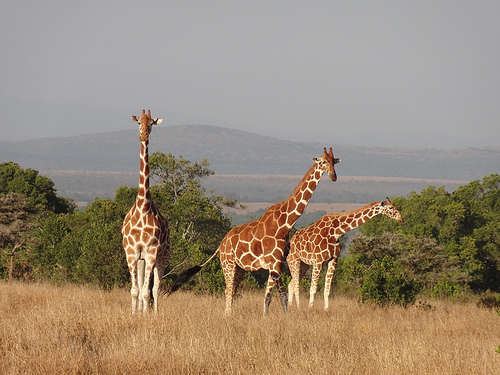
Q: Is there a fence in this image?
A: No, there are no fences.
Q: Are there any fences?
A: No, there are no fences.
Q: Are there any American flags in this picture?
A: No, there are no American flags.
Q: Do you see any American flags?
A: No, there are no American flags.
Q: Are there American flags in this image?
A: No, there are no American flags.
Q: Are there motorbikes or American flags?
A: No, there are no American flags or motorbikes.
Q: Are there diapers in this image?
A: No, there are no diapers.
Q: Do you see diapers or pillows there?
A: No, there are no diapers or pillows.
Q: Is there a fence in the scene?
A: No, there are no fences.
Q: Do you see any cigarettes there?
A: No, there are no cigarettes.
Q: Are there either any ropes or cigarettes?
A: No, there are no cigarettes or ropes.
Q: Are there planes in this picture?
A: No, there are no planes.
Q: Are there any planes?
A: No, there are no planes.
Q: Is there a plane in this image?
A: No, there are no airplanes.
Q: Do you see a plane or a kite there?
A: No, there are no airplanes or kites.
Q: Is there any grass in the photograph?
A: Yes, there is grass.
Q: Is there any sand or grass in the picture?
A: Yes, there is grass.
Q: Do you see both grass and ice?
A: No, there is grass but no ice.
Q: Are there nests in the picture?
A: No, there are no nests.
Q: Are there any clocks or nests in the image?
A: No, there are no nests or clocks.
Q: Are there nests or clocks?
A: No, there are no nests or clocks.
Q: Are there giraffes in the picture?
A: Yes, there is a giraffe.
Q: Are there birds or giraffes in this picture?
A: Yes, there is a giraffe.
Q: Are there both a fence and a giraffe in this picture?
A: No, there is a giraffe but no fences.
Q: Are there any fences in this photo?
A: No, there are no fences.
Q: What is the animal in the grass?
A: The animal is a giraffe.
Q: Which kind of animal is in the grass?
A: The animal is a giraffe.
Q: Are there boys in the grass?
A: No, there is a giraffe in the grass.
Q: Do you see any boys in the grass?
A: No, there is a giraffe in the grass.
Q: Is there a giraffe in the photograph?
A: Yes, there is a giraffe.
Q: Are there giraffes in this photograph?
A: Yes, there is a giraffe.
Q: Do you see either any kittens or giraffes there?
A: Yes, there is a giraffe.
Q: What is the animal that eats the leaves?
A: The animal is a giraffe.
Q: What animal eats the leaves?
A: The animal is a giraffe.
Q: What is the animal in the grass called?
A: The animal is a giraffe.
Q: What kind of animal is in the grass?
A: The animal is a giraffe.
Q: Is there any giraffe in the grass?
A: Yes, there is a giraffe in the grass.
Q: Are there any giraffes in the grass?
A: Yes, there is a giraffe in the grass.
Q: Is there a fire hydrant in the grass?
A: No, there is a giraffe in the grass.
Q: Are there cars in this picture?
A: No, there are no cars.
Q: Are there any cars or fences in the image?
A: No, there are no cars or fences.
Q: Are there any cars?
A: No, there are no cars.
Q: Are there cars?
A: No, there are no cars.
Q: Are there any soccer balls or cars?
A: No, there are no cars or soccer balls.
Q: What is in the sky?
A: The clouds are in the sky.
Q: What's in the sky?
A: The clouds are in the sky.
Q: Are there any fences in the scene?
A: No, there are no fences.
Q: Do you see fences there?
A: No, there are no fences.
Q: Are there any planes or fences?
A: No, there are no fences or planes.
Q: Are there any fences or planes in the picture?
A: No, there are no fences or planes.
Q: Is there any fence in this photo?
A: No, there are no fences.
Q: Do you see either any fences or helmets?
A: No, there are no fences or helmets.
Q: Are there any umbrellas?
A: No, there are no umbrellas.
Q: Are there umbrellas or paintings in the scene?
A: No, there are no umbrellas or paintings.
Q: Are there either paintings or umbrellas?
A: No, there are no umbrellas or paintings.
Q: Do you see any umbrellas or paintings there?
A: No, there are no umbrellas or paintings.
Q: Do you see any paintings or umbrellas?
A: No, there are no umbrellas or paintings.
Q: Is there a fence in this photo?
A: No, there are no fences.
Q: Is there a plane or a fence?
A: No, there are no fences or airplanes.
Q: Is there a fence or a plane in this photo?
A: No, there are no fences or airplanes.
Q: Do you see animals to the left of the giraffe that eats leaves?
A: Yes, there are animals to the left of the giraffe.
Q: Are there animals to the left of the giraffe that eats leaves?
A: Yes, there are animals to the left of the giraffe.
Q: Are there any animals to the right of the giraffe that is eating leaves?
A: No, the animals are to the left of the giraffe.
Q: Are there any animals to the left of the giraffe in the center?
A: Yes, there are animals to the left of the giraffe.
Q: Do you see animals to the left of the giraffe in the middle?
A: Yes, there are animals to the left of the giraffe.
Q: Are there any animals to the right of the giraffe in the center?
A: No, the animals are to the left of the giraffe.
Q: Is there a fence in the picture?
A: No, there are no fences.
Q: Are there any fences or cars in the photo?
A: No, there are no fences or cars.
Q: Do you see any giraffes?
A: Yes, there is a giraffe.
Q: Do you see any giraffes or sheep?
A: Yes, there is a giraffe.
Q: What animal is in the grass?
A: The animal is a giraffe.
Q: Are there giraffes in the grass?
A: Yes, there is a giraffe in the grass.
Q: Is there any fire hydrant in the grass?
A: No, there is a giraffe in the grass.